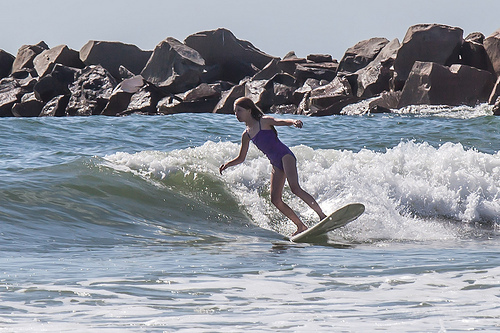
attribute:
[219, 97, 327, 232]
woman — young, red, long, girl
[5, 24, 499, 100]
boulders — grey, large, glistening, big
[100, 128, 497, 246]
surf — rolling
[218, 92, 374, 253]
surfboard — young, white, alone, inclined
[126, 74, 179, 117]
animal — large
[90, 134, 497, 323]
break — choppy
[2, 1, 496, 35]
sky — blue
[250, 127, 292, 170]
swimsuit — purple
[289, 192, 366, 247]
surfboard — white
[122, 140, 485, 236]
wave — breaking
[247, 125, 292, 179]
swimsuit — purple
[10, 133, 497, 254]
wave — white, large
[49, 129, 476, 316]
waters — choppy, blue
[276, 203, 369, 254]
surfboard — white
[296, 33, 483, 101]
rock — large, gray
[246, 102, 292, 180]
bathing suit — purple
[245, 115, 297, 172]
bathing suit — purple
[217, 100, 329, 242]
girl — young, little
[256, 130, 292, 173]
bathing suit — purple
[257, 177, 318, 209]
knees — bent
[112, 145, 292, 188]
water — white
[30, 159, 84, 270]
water — smooth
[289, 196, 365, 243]
board — white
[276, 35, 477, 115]
rocks — curved, flat, jagged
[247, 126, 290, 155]
bathing suit — purple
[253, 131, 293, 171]
swimsuit — purple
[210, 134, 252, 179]
arms — extended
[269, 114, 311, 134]
arms — extended